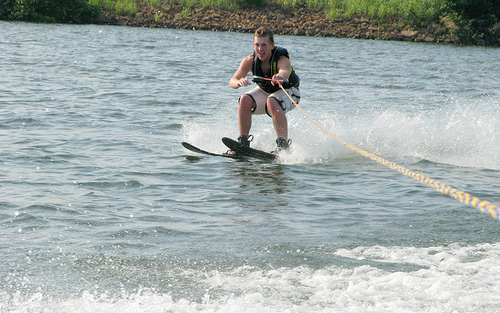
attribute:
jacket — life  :
[243, 50, 303, 94]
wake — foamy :
[354, 257, 480, 309]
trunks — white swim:
[240, 81, 304, 115]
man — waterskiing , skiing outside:
[225, 23, 305, 150]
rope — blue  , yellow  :
[291, 92, 483, 212]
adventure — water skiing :
[5, 20, 484, 305]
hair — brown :
[254, 26, 274, 39]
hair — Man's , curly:
[253, 26, 274, 35]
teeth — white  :
[255, 53, 267, 60]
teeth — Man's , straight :
[254, 47, 273, 54]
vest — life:
[243, 45, 302, 93]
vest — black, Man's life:
[244, 47, 303, 99]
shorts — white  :
[239, 82, 304, 114]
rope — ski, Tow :
[282, 82, 484, 222]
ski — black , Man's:
[180, 123, 317, 175]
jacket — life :
[244, 51, 302, 98]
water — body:
[16, 182, 406, 309]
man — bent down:
[230, 28, 306, 152]